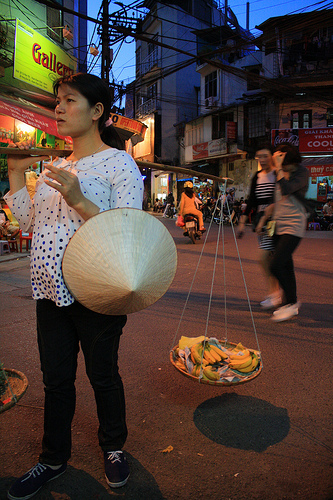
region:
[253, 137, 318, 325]
person walking on the street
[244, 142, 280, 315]
person walking on the street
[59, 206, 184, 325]
hat woven of grass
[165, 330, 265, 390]
bananas on a tray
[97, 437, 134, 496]
black shoe with white laces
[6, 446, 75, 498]
black shoe with white laces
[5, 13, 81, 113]
yellow sign with red writing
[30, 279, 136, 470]
pair of black pants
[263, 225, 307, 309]
pair of black pants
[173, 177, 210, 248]
two people on a motorcycle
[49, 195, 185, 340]
woman carrying straw hat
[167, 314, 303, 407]
woman carrying tray of bananas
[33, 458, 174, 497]
woman wearing black shoes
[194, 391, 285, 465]
shadow of tray of bananas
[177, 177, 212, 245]
person riding on scooter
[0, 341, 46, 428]
part of tray on chains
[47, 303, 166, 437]
woman wearing black pants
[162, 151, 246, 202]
pole connected to tray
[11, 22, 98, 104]
yellow sign with red lettering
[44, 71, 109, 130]
woman with black hair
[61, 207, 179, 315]
tan conical bamboo hat on arm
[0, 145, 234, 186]
woman carrying a wooden pole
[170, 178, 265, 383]
white strings attached to pole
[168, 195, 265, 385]
strings suspend wooden plate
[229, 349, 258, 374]
bananas on plate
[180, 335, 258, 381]
towel under yellow bananas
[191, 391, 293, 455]
shadow under plate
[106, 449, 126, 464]
white laces on black shies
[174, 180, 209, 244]
person riding motorcycle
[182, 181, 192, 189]
yellow helmet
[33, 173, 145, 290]
a hat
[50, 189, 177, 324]
a hat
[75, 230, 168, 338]
a hat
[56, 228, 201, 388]
a hat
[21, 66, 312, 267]
a busy street in an Asian city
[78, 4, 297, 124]
it is dusk in this city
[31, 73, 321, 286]
the street lights are on and people are out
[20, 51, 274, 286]
this lady is carrying something on her shoulders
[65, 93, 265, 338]
this is how some people carry goods from the market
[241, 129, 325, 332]
two girls in the background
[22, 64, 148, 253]
this Asian woman is young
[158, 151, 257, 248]
these people are busy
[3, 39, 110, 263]
some kind of restaurant behind the lady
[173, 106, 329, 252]
more businesses in the area